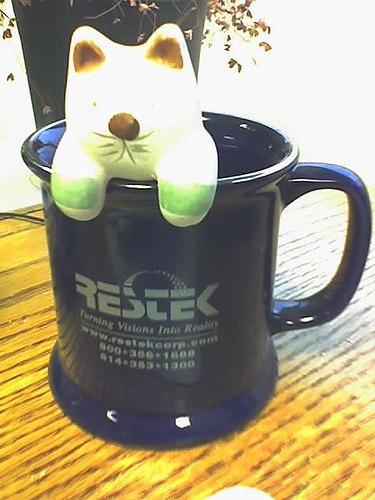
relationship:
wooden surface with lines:
[16, 437, 65, 490] [292, 429, 343, 475]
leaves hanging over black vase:
[1, 3, 277, 107] [8, 1, 207, 130]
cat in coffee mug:
[47, 21, 214, 228] [21, 105, 370, 453]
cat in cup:
[47, 21, 214, 228] [23, 17, 374, 486]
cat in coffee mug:
[47, 21, 214, 228] [18, 112, 371, 450]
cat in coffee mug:
[53, 26, 209, 218] [21, 105, 370, 453]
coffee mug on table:
[2, 55, 352, 258] [1, 184, 372, 498]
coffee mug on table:
[21, 105, 370, 453] [1, 184, 372, 498]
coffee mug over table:
[21, 105, 370, 453] [1, 184, 372, 498]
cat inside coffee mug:
[47, 21, 214, 228] [21, 105, 370, 453]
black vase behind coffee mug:
[8, 1, 207, 130] [21, 105, 370, 453]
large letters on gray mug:
[70, 272, 225, 322] [19, 110, 372, 454]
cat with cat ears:
[47, 21, 214, 228] [68, 24, 110, 73]